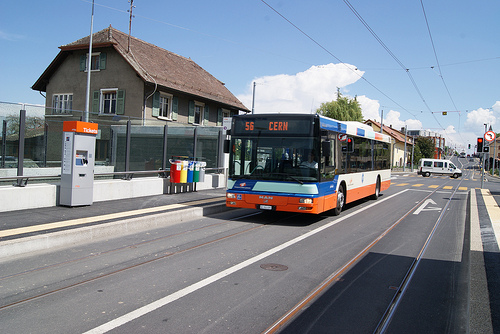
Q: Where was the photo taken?
A: It was taken at the road.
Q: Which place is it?
A: It is a road.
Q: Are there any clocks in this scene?
A: Yes, there is a clock.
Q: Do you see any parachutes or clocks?
A: Yes, there is a clock.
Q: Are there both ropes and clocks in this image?
A: No, there is a clock but no ropes.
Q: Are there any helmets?
A: No, there are no helmets.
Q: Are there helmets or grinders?
A: No, there are no helmets or grinders.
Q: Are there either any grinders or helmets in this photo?
A: No, there are no helmets or grinders.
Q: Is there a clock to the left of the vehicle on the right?
A: Yes, there is a clock to the left of the car.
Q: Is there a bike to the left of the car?
A: No, there is a clock to the left of the car.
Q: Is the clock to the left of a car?
A: Yes, the clock is to the left of a car.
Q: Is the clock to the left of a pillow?
A: No, the clock is to the left of a car.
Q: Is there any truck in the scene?
A: No, there are no trucks.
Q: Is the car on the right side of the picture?
A: Yes, the car is on the right of the image.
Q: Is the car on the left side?
A: No, the car is on the right of the image.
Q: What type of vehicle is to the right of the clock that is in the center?
A: The vehicle is a car.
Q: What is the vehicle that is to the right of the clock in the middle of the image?
A: The vehicle is a car.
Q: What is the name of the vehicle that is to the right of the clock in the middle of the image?
A: The vehicle is a car.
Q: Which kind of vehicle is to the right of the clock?
A: The vehicle is a car.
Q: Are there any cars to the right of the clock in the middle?
A: Yes, there is a car to the right of the clock.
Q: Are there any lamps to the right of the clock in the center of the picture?
A: No, there is a car to the right of the clock.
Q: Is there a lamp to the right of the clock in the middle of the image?
A: No, there is a car to the right of the clock.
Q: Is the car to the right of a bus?
A: No, the car is to the right of a clock.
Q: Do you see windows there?
A: Yes, there is a window.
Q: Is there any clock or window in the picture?
A: Yes, there is a window.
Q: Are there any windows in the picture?
A: Yes, there is a window.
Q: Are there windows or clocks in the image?
A: Yes, there is a window.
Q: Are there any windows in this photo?
A: Yes, there is a window.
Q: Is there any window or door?
A: Yes, there is a window.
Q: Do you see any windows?
A: Yes, there is a window.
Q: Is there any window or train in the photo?
A: Yes, there is a window.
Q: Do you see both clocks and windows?
A: Yes, there are both a window and a clock.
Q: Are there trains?
A: No, there are no trains.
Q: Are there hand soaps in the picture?
A: No, there are no hand soaps.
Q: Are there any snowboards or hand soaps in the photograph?
A: No, there are no hand soaps or snowboards.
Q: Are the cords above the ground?
A: Yes, the cords are above the ground.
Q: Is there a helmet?
A: No, there are no helmets.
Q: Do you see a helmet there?
A: No, there are no helmets.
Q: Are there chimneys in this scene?
A: No, there are no chimneys.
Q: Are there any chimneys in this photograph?
A: No, there are no chimneys.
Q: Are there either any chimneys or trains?
A: No, there are no chimneys or trains.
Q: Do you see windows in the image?
A: Yes, there is a window.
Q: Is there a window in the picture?
A: Yes, there is a window.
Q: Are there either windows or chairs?
A: Yes, there is a window.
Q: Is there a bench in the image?
A: No, there are no benches.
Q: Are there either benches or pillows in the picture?
A: No, there are no benches or pillows.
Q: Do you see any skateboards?
A: No, there are no skateboards.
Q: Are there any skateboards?
A: No, there are no skateboards.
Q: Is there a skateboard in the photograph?
A: No, there are no skateboards.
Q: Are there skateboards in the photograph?
A: No, there are no skateboards.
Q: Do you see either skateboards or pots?
A: No, there are no skateboards or pots.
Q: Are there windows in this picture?
A: Yes, there is a window.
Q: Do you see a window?
A: Yes, there is a window.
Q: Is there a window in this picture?
A: Yes, there is a window.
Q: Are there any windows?
A: Yes, there is a window.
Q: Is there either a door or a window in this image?
A: Yes, there is a window.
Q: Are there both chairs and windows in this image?
A: No, there is a window but no chairs.